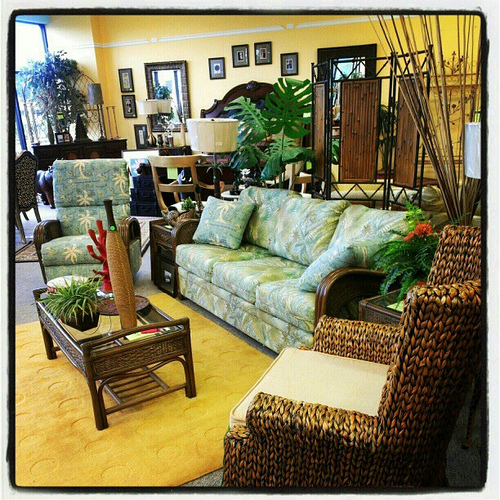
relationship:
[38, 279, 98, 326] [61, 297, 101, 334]
plant in planter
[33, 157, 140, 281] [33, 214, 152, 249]
chair with arms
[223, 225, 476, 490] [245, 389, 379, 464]
chair with rattan arm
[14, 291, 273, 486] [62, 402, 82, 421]
rug with circle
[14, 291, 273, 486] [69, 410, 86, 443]
rug with circle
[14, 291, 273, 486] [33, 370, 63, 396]
rug with circle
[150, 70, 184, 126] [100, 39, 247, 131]
framed mirror on wall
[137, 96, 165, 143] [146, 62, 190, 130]
lamp in front of mirror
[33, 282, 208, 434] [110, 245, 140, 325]
table with decoration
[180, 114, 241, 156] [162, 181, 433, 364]
lamp shade to left of couch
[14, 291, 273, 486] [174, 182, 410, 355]
rug in front of couch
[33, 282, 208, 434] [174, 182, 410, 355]
table in front of couch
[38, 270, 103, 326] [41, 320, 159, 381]
plant on table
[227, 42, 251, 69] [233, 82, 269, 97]
picture above bed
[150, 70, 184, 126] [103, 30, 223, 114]
framed mirror on wall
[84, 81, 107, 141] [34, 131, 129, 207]
lamp on dresser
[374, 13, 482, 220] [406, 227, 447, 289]
sticks in vase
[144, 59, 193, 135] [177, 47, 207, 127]
framed mirror on wall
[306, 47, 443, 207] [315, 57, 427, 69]
bamboo divider in frame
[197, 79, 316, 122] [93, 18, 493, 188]
headboard against wall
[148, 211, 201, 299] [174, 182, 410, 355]
side table next to couch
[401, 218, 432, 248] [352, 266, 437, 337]
flower on table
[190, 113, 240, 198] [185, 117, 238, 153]
lamp has lamp shade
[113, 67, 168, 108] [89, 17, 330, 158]
pictures hanging on wall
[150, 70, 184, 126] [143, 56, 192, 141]
framed mirror in frame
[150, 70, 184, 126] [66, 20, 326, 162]
framed mirror hanging on wall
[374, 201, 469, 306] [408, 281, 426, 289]
plant in vase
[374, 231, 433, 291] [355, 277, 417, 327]
plant on table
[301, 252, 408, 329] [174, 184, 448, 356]
rattan arm on couch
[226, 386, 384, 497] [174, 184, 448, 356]
rattan arm on couch